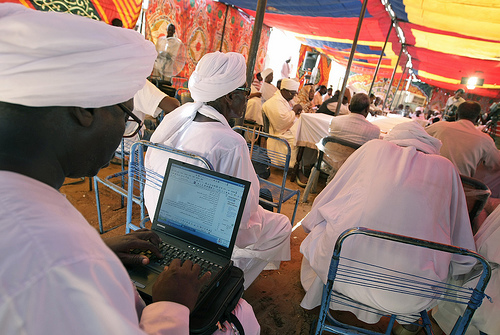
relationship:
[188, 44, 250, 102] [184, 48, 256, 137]
turban on a head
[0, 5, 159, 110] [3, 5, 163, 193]
turban on a head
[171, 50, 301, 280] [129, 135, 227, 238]
person sitting in a chair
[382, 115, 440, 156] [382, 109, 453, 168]
white turban on head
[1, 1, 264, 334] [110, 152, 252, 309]
man using a laptop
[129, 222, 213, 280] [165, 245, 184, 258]
fingers on keyboard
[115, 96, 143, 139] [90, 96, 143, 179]
glasses on face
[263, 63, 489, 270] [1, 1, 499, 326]
people in one room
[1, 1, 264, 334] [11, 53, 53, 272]
man wearing white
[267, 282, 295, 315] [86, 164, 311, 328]
dirt on floor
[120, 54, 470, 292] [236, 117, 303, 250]
men sitting blue chairs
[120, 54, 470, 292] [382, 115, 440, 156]
men wearing white turban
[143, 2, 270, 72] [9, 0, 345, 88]
mural on wall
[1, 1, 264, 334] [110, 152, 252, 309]
man working on a laptop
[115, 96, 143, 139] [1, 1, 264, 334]
glasses on man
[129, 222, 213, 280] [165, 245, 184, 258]
hands on keyboard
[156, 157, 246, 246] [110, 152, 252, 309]
screen of laptop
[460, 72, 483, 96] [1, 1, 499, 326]
light at front of room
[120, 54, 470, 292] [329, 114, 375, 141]
men wearing white shirts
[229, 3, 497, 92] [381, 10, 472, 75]
stripes on ceiling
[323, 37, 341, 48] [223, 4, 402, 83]
part of surface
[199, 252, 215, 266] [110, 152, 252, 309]
part of a laptop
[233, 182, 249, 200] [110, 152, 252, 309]
edge of a laptop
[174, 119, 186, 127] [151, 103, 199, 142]
part of a cloth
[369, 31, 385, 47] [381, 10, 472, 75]
fabric on ceiling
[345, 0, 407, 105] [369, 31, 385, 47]
poles holding up fabric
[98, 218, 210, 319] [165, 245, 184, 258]
hands on keyboard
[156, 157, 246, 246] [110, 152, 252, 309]
screen on laptop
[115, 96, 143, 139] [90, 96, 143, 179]
glasses on man face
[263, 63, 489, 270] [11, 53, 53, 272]
people dressed in white